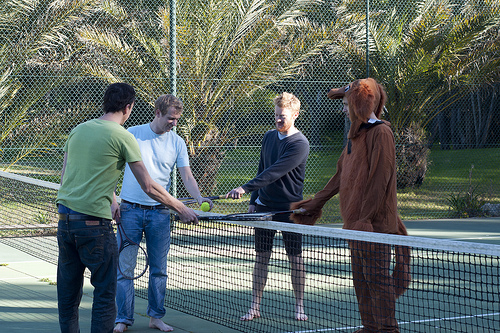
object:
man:
[225, 92, 310, 322]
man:
[289, 77, 413, 333]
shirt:
[54, 119, 145, 221]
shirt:
[120, 123, 190, 206]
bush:
[23, 0, 341, 201]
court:
[0, 218, 500, 333]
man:
[110, 94, 214, 333]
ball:
[199, 202, 211, 212]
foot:
[240, 308, 261, 321]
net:
[0, 172, 499, 333]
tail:
[392, 219, 412, 299]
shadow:
[396, 261, 499, 333]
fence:
[0, 0, 499, 237]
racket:
[200, 212, 273, 221]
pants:
[115, 198, 173, 327]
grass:
[1, 148, 500, 237]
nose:
[276, 116, 281, 122]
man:
[55, 82, 199, 333]